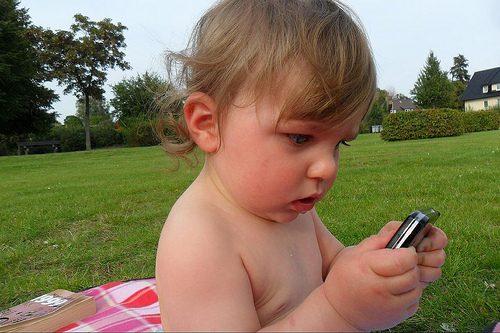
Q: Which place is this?
A: It is a yard.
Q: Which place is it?
A: It is a yard.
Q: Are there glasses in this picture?
A: No, there are no glasses.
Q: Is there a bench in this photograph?
A: Yes, there is a bench.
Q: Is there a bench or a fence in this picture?
A: Yes, there is a bench.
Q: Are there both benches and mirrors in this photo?
A: No, there is a bench but no mirrors.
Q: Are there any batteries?
A: No, there are no batteries.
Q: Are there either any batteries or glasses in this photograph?
A: No, there are no batteries or glasses.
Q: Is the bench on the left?
A: Yes, the bench is on the left of the image.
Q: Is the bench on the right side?
A: No, the bench is on the left of the image.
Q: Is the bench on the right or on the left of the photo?
A: The bench is on the left of the image.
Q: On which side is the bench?
A: The bench is on the left of the image.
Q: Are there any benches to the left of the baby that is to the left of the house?
A: Yes, there is a bench to the left of the baby.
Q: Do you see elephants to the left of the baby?
A: No, there is a bench to the left of the baby.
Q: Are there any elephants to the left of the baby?
A: No, there is a bench to the left of the baby.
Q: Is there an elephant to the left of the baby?
A: No, there is a bench to the left of the baby.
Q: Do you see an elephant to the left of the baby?
A: No, there is a bench to the left of the baby.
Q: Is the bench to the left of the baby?
A: Yes, the bench is to the left of the baby.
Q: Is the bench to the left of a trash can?
A: No, the bench is to the left of the baby.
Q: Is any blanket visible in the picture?
A: Yes, there is a blanket.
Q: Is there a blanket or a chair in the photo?
A: Yes, there is a blanket.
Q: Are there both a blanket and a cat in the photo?
A: No, there is a blanket but no cats.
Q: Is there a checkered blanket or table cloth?
A: Yes, there is a checkered blanket.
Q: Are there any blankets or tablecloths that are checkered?
A: Yes, the blanket is checkered.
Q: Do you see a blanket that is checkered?
A: Yes, there is a checkered blanket.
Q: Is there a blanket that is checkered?
A: Yes, there is a blanket that is checkered.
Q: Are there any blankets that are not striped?
A: Yes, there is a checkered blanket.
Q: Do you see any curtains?
A: No, there are no curtains.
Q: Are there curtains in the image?
A: No, there are no curtains.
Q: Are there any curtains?
A: No, there are no curtains.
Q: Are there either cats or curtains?
A: No, there are no curtains or cats.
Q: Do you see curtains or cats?
A: No, there are no curtains or cats.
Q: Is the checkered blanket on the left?
A: Yes, the blanket is on the left of the image.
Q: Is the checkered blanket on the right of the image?
A: No, the blanket is on the left of the image.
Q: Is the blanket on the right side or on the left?
A: The blanket is on the left of the image.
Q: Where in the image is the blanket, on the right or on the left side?
A: The blanket is on the left of the image.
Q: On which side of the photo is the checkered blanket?
A: The blanket is on the left of the image.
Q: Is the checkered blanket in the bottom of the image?
A: Yes, the blanket is in the bottom of the image.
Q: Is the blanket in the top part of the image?
A: No, the blanket is in the bottom of the image.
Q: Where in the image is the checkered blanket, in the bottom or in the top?
A: The blanket is in the bottom of the image.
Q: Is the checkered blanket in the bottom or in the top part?
A: The blanket is in the bottom of the image.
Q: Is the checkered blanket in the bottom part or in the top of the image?
A: The blanket is in the bottom of the image.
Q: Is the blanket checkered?
A: Yes, the blanket is checkered.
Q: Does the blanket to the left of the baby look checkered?
A: Yes, the blanket is checkered.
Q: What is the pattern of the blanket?
A: The blanket is checkered.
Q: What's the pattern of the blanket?
A: The blanket is checkered.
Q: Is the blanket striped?
A: No, the blanket is checkered.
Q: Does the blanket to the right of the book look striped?
A: No, the blanket is checkered.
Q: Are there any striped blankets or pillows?
A: No, there is a blanket but it is checkered.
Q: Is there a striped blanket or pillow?
A: No, there is a blanket but it is checkered.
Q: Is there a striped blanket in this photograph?
A: No, there is a blanket but it is checkered.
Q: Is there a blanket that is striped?
A: No, there is a blanket but it is checkered.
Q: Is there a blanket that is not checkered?
A: No, there is a blanket but it is checkered.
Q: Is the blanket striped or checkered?
A: The blanket is checkered.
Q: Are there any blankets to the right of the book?
A: Yes, there is a blanket to the right of the book.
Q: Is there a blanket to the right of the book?
A: Yes, there is a blanket to the right of the book.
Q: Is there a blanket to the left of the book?
A: No, the blanket is to the right of the book.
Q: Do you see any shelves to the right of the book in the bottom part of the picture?
A: No, there is a blanket to the right of the book.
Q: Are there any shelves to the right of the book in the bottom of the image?
A: No, there is a blanket to the right of the book.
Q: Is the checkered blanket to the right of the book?
A: Yes, the blanket is to the right of the book.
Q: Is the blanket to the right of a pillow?
A: No, the blanket is to the right of the book.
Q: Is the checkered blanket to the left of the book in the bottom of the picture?
A: No, the blanket is to the right of the book.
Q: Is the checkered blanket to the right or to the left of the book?
A: The blanket is to the right of the book.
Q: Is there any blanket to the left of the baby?
A: Yes, there is a blanket to the left of the baby.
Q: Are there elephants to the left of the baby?
A: No, there is a blanket to the left of the baby.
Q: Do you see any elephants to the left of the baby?
A: No, there is a blanket to the left of the baby.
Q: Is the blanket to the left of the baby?
A: Yes, the blanket is to the left of the baby.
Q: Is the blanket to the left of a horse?
A: No, the blanket is to the left of the baby.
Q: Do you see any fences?
A: No, there are no fences.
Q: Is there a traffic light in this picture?
A: No, there are no traffic lights.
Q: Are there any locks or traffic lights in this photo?
A: No, there are no traffic lights or locks.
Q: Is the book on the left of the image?
A: Yes, the book is on the left of the image.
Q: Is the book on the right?
A: No, the book is on the left of the image.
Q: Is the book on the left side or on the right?
A: The book is on the left of the image.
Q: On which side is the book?
A: The book is on the left of the image.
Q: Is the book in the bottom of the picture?
A: Yes, the book is in the bottom of the image.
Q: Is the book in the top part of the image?
A: No, the book is in the bottom of the image.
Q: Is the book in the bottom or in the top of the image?
A: The book is in the bottom of the image.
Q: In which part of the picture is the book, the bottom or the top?
A: The book is in the bottom of the image.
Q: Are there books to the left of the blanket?
A: Yes, there is a book to the left of the blanket.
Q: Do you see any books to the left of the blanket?
A: Yes, there is a book to the left of the blanket.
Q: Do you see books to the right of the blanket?
A: No, the book is to the left of the blanket.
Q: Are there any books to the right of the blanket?
A: No, the book is to the left of the blanket.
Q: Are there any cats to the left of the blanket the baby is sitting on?
A: No, there is a book to the left of the blanket.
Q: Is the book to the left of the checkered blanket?
A: Yes, the book is to the left of the blanket.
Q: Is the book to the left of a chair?
A: No, the book is to the left of the blanket.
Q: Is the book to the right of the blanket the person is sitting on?
A: No, the book is to the left of the blanket.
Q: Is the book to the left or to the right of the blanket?
A: The book is to the left of the blanket.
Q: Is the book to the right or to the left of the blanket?
A: The book is to the left of the blanket.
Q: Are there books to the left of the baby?
A: Yes, there is a book to the left of the baby.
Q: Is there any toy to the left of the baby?
A: No, there is a book to the left of the baby.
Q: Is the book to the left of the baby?
A: Yes, the book is to the left of the baby.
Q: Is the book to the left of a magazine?
A: No, the book is to the left of the baby.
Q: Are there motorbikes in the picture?
A: No, there are no motorbikes.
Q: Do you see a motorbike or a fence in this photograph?
A: No, there are no motorcycles or fences.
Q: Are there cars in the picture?
A: No, there are no cars.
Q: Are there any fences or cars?
A: No, there are no cars or fences.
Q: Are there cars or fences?
A: No, there are no cars or fences.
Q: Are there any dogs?
A: No, there are no dogs.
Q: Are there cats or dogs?
A: No, there are no dogs or cats.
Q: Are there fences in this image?
A: No, there are no fences.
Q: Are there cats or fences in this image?
A: No, there are no fences or cats.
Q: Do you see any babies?
A: Yes, there is a baby.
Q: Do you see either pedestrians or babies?
A: Yes, there is a baby.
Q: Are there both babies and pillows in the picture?
A: No, there is a baby but no pillows.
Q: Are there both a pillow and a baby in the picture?
A: No, there is a baby but no pillows.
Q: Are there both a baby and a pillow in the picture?
A: No, there is a baby but no pillows.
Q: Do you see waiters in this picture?
A: No, there are no waiters.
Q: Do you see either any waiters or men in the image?
A: No, there are no waiters or men.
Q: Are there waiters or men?
A: No, there are no waiters or men.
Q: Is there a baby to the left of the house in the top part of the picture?
A: Yes, there is a baby to the left of the house.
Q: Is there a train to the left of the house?
A: No, there is a baby to the left of the house.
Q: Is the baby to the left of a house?
A: Yes, the baby is to the left of a house.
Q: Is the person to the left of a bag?
A: No, the baby is to the left of a house.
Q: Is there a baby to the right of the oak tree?
A: Yes, there is a baby to the right of the oak tree.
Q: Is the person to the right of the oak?
A: Yes, the baby is to the right of the oak.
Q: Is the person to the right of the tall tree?
A: Yes, the baby is to the right of the oak.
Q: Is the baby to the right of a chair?
A: No, the baby is to the right of the oak.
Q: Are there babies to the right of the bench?
A: Yes, there is a baby to the right of the bench.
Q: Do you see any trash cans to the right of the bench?
A: No, there is a baby to the right of the bench.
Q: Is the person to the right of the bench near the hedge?
A: Yes, the baby is to the right of the bench.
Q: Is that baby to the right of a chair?
A: No, the baby is to the right of the bench.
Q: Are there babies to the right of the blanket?
A: Yes, there is a baby to the right of the blanket.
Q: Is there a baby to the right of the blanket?
A: Yes, there is a baby to the right of the blanket.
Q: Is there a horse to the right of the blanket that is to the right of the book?
A: No, there is a baby to the right of the blanket.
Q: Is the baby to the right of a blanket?
A: Yes, the baby is to the right of a blanket.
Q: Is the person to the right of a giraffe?
A: No, the baby is to the right of a blanket.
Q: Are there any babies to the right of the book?
A: Yes, there is a baby to the right of the book.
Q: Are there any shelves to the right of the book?
A: No, there is a baby to the right of the book.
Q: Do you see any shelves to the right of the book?
A: No, there is a baby to the right of the book.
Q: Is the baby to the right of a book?
A: Yes, the baby is to the right of a book.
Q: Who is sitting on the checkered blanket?
A: The baby is sitting on the blanket.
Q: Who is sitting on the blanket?
A: The baby is sitting on the blanket.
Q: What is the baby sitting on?
A: The baby is sitting on the blanket.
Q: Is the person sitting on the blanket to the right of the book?
A: Yes, the baby is sitting on the blanket.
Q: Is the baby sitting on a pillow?
A: No, the baby is sitting on the blanket.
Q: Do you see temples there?
A: No, there are no temples.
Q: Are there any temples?
A: No, there are no temples.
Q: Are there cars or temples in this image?
A: No, there are no temples or cars.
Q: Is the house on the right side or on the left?
A: The house is on the right of the image.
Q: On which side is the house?
A: The house is on the right of the image.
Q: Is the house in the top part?
A: Yes, the house is in the top of the image.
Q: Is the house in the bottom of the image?
A: No, the house is in the top of the image.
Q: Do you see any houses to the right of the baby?
A: Yes, there is a house to the right of the baby.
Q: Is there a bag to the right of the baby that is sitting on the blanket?
A: No, there is a house to the right of the baby.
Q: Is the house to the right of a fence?
A: No, the house is to the right of the baby.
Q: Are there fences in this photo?
A: No, there are no fences.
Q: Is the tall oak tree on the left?
A: Yes, the oak tree is on the left of the image.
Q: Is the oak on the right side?
A: No, the oak is on the left of the image.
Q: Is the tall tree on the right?
A: No, the oak is on the left of the image.